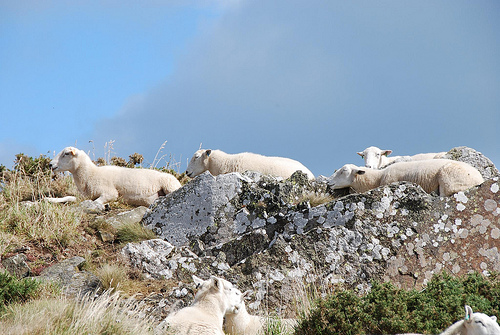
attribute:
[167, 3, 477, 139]
clouds — white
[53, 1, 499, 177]
cloud — white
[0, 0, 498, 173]
sky — blue